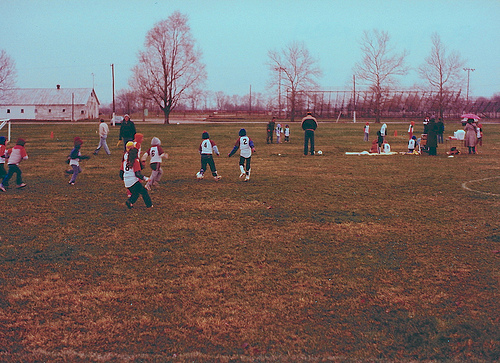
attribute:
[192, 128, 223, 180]
child — small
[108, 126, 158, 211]
girl — young, black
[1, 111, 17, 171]
net — white framed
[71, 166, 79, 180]
pants — purple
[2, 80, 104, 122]
barn — large, old, white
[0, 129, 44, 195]
child jeans — blue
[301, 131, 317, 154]
pants — black